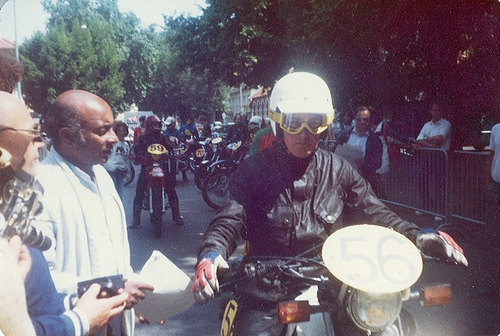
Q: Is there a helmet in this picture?
A: Yes, there is a helmet.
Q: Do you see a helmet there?
A: Yes, there is a helmet.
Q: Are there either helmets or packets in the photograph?
A: Yes, there is a helmet.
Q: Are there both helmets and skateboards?
A: No, there is a helmet but no skateboards.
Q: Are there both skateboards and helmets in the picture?
A: No, there is a helmet but no skateboards.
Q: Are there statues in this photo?
A: No, there are no statues.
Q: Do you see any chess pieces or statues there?
A: No, there are no statues or chess pieces.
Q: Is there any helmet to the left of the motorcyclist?
A: Yes, there is a helmet to the left of the motorcyclist.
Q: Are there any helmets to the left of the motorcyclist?
A: Yes, there is a helmet to the left of the motorcyclist.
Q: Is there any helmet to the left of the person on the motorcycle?
A: Yes, there is a helmet to the left of the motorcyclist.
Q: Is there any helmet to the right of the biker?
A: No, the helmet is to the left of the biker.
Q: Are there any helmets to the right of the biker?
A: No, the helmet is to the left of the biker.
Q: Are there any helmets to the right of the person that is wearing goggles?
A: No, the helmet is to the left of the biker.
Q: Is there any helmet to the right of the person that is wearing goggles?
A: No, the helmet is to the left of the biker.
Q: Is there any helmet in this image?
A: Yes, there is a helmet.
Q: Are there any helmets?
A: Yes, there is a helmet.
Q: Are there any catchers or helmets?
A: Yes, there is a helmet.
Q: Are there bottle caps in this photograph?
A: No, there are no bottle caps.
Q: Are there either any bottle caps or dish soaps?
A: No, there are no bottle caps or dish soaps.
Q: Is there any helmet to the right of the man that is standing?
A: Yes, there is a helmet to the right of the man.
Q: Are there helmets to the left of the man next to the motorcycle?
A: No, the helmet is to the right of the man.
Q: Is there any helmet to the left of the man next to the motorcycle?
A: No, the helmet is to the right of the man.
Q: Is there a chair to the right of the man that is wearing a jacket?
A: No, there is a helmet to the right of the man.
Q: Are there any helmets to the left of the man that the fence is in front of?
A: Yes, there is a helmet to the left of the man.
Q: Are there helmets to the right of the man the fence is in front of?
A: No, the helmet is to the left of the man.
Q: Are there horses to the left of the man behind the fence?
A: No, there is a helmet to the left of the man.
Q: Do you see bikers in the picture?
A: Yes, there is a biker.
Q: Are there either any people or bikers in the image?
A: Yes, there is a biker.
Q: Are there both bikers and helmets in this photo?
A: Yes, there are both a biker and a helmet.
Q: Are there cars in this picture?
A: No, there are no cars.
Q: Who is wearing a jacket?
A: The motorcyclist is wearing a jacket.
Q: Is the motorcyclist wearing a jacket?
A: Yes, the motorcyclist is wearing a jacket.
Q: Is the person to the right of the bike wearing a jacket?
A: Yes, the motorcyclist is wearing a jacket.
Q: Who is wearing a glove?
A: The motorcyclist is wearing a glove.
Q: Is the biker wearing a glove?
A: Yes, the biker is wearing a glove.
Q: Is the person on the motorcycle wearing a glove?
A: Yes, the biker is wearing a glove.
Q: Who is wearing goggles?
A: The biker is wearing goggles.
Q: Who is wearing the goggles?
A: The biker is wearing goggles.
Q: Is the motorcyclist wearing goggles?
A: Yes, the motorcyclist is wearing goggles.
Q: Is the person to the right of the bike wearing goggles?
A: Yes, the motorcyclist is wearing goggles.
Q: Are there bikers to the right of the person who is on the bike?
A: Yes, there is a biker to the right of the person.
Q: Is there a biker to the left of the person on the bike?
A: No, the biker is to the right of the person.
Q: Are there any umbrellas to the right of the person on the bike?
A: No, there is a biker to the right of the person.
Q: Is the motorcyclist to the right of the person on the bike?
A: Yes, the motorcyclist is to the right of the person.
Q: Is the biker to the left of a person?
A: No, the biker is to the right of a person.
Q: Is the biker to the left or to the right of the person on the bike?
A: The biker is to the right of the person.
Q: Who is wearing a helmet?
A: The motorcyclist is wearing a helmet.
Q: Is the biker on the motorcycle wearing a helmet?
A: Yes, the motorcyclist is wearing a helmet.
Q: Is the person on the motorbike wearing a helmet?
A: Yes, the motorcyclist is wearing a helmet.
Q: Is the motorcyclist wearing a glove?
A: Yes, the motorcyclist is wearing a glove.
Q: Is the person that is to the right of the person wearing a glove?
A: Yes, the motorcyclist is wearing a glove.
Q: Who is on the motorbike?
A: The motorcyclist is on the motorbike.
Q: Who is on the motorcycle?
A: The motorcyclist is on the motorbike.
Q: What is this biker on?
A: The biker is on the motorbike.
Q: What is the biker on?
A: The biker is on the motorbike.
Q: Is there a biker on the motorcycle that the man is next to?
A: Yes, there is a biker on the motorcycle.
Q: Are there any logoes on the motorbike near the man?
A: No, there is a biker on the motorbike.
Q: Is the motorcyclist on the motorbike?
A: Yes, the motorcyclist is on the motorbike.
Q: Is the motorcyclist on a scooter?
A: No, the motorcyclist is on the motorbike.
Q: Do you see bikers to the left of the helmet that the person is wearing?
A: No, the biker is to the right of the helmet.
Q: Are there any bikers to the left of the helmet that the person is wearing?
A: No, the biker is to the right of the helmet.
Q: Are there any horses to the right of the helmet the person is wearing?
A: No, there is a biker to the right of the helmet.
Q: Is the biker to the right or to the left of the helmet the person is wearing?
A: The biker is to the right of the helmet.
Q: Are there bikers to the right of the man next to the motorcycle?
A: Yes, there is a biker to the right of the man.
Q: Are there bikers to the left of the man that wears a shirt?
A: No, the biker is to the right of the man.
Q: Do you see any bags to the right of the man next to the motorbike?
A: No, there is a biker to the right of the man.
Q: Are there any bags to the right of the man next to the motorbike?
A: No, there is a biker to the right of the man.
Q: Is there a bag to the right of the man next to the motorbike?
A: No, there is a biker to the right of the man.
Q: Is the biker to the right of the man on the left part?
A: Yes, the biker is to the right of the man.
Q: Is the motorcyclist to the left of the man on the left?
A: No, the motorcyclist is to the right of the man.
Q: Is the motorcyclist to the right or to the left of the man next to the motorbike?
A: The motorcyclist is to the right of the man.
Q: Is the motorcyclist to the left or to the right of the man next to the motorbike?
A: The motorcyclist is to the right of the man.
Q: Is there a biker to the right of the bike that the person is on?
A: Yes, there is a biker to the right of the bike.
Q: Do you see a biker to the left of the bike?
A: No, the biker is to the right of the bike.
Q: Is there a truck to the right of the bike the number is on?
A: No, there is a biker to the right of the bike.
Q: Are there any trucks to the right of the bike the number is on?
A: No, there is a biker to the right of the bike.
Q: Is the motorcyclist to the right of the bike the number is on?
A: Yes, the motorcyclist is to the right of the bike.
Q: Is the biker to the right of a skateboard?
A: No, the biker is to the right of the bike.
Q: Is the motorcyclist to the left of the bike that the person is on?
A: No, the motorcyclist is to the right of the bike.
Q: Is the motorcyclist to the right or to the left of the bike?
A: The motorcyclist is to the right of the bike.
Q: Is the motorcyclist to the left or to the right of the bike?
A: The motorcyclist is to the right of the bike.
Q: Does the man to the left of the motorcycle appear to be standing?
A: Yes, the man is standing.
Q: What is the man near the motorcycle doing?
A: The man is standing.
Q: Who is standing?
A: The man is standing.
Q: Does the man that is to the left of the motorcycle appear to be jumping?
A: No, the man is standing.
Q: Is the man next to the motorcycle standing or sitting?
A: The man is standing.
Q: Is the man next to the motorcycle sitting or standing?
A: The man is standing.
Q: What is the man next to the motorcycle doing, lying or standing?
A: The man is standing.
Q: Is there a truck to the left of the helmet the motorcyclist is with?
A: No, there is a man to the left of the helmet.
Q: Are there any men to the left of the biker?
A: Yes, there is a man to the left of the biker.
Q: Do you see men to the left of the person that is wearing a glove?
A: Yes, there is a man to the left of the biker.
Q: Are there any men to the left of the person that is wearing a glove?
A: Yes, there is a man to the left of the biker.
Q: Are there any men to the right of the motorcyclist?
A: No, the man is to the left of the motorcyclist.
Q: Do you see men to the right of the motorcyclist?
A: No, the man is to the left of the motorcyclist.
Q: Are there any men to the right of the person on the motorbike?
A: No, the man is to the left of the motorcyclist.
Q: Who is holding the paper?
A: The man is holding the paper.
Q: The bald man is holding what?
A: The man is holding the paper.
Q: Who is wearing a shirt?
A: The man is wearing a shirt.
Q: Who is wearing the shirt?
A: The man is wearing a shirt.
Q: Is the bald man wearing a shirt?
A: Yes, the man is wearing a shirt.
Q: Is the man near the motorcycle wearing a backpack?
A: No, the man is wearing a shirt.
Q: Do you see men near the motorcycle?
A: Yes, there is a man near the motorcycle.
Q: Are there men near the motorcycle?
A: Yes, there is a man near the motorcycle.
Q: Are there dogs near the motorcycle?
A: No, there is a man near the motorcycle.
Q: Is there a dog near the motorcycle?
A: No, there is a man near the motorcycle.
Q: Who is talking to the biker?
A: The man is talking to the biker.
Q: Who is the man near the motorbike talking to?
A: The man is talking to a motorcyclist.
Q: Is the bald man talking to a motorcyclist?
A: Yes, the man is talking to a motorcyclist.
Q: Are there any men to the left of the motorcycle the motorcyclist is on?
A: Yes, there is a man to the left of the motorbike.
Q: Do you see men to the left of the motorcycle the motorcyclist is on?
A: Yes, there is a man to the left of the motorbike.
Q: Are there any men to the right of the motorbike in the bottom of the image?
A: No, the man is to the left of the motorbike.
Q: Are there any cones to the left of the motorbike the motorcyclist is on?
A: No, there is a man to the left of the motorcycle.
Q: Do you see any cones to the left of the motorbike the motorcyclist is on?
A: No, there is a man to the left of the motorcycle.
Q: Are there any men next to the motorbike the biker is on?
A: Yes, there is a man next to the motorcycle.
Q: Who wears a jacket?
A: The man wears a jacket.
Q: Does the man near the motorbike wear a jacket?
A: Yes, the man wears a jacket.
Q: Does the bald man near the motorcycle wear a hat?
A: No, the man wears a jacket.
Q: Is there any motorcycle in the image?
A: Yes, there is a motorcycle.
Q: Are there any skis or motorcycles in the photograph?
A: Yes, there is a motorcycle.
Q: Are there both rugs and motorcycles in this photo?
A: No, there is a motorcycle but no rugs.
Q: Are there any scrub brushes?
A: No, there are no scrub brushes.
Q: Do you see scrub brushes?
A: No, there are no scrub brushes.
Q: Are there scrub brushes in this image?
A: No, there are no scrub brushes.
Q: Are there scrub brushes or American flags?
A: No, there are no scrub brushes or American flags.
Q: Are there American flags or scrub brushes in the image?
A: No, there are no scrub brushes or American flags.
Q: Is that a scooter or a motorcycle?
A: That is a motorcycle.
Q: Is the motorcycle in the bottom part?
A: Yes, the motorcycle is in the bottom of the image.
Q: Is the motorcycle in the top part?
A: No, the motorcycle is in the bottom of the image.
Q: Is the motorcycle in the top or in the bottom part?
A: The motorcycle is in the bottom of the image.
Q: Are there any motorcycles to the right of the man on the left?
A: Yes, there is a motorcycle to the right of the man.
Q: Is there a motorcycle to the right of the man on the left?
A: Yes, there is a motorcycle to the right of the man.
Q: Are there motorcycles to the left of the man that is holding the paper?
A: No, the motorcycle is to the right of the man.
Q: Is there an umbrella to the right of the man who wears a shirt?
A: No, there is a motorcycle to the right of the man.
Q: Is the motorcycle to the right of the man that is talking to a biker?
A: Yes, the motorcycle is to the right of the man.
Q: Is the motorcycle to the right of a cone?
A: No, the motorcycle is to the right of the man.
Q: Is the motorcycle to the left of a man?
A: No, the motorcycle is to the right of a man.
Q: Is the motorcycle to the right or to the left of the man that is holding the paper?
A: The motorcycle is to the right of the man.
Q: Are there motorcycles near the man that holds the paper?
A: Yes, there is a motorcycle near the man.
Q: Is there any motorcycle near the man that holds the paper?
A: Yes, there is a motorcycle near the man.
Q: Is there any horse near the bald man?
A: No, there is a motorcycle near the man.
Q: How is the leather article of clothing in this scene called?
A: The clothing item is a jacket.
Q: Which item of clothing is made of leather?
A: The clothing item is a jacket.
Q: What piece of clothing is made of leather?
A: The clothing item is a jacket.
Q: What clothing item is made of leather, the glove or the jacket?
A: The jacket is made of leather.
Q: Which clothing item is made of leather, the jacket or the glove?
A: The jacket is made of leather.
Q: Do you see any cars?
A: No, there are no cars.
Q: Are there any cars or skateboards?
A: No, there are no cars or skateboards.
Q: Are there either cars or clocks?
A: No, there are no cars or clocks.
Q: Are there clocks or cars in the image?
A: No, there are no cars or clocks.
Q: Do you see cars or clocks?
A: No, there are no cars or clocks.